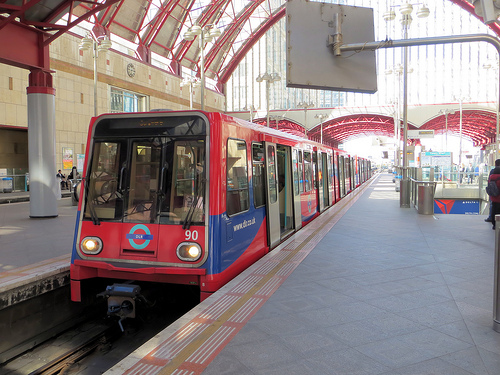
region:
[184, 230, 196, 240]
the 90 on the front of the train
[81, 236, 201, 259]
the headlights on the train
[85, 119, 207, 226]
the windshield on the train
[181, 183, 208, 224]
the windshield wiper on the train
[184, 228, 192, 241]
the 9 on the front of the train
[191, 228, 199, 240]
the 0 on the front of the train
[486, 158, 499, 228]
the person standing to the side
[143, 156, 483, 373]
the walkway near the train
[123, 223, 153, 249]
the circle on the front of the train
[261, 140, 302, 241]
the first opened door on the train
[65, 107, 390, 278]
A red and blue train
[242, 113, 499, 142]
Red archways on the ceiling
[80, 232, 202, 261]
Headlights on a train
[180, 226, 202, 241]
the number 90 on the train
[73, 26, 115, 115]
a light pole with four lights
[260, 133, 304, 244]
an open door on a train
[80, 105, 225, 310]
The front of a train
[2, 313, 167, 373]
The tracks in a train station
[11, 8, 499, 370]
A train in a train station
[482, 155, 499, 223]
A person in a train station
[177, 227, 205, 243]
white numbers on bus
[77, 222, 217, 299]
lights on front of bus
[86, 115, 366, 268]
red train on tracks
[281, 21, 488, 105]
silver sign by train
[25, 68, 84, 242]
white pole by train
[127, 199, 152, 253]
blue circle on train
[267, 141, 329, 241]
open door on train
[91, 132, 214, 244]
front window on train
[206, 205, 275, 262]
blue paint on side of train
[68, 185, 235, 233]
wipers on front of train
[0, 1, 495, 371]
a public transit train station.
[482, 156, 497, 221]
a passenger walking from the train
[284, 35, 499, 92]
arrival and departure destination board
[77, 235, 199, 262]
two headlights on front of the train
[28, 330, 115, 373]
tracks on the railway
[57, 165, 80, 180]
two people on the other side of the train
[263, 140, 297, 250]
an opened door on the left side of the train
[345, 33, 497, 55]
a gray metal pole attached to the destination board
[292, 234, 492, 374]
pedestrian walkway at the train station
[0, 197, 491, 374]
Two pedestrian walkways in the train station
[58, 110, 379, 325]
The train is coming in the station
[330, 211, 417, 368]
The ground is made of concrete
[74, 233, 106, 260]
The headlight is on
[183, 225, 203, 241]
The number on the bus is 90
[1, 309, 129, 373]
The train track is gray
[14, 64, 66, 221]
The column is gray and red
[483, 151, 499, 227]
A person is standing in the train station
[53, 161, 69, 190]
A man sitting in the train station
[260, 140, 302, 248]
The door to the train is open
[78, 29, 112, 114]
The light pole in the train station